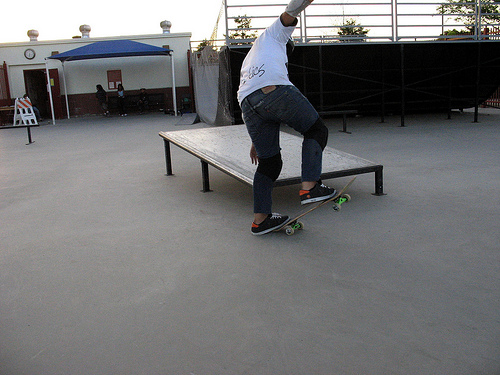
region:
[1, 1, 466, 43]
light in daytime sky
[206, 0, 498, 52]
railing on top of wall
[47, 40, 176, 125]
blue canvas on poles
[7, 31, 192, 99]
white wall of building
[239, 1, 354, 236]
person on tilted skateboard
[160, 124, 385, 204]
tilted surface on legs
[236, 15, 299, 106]
white short sleeved shirt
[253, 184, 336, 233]
two sneakers on feet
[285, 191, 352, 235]
wheels under tilted skateboard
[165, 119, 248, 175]
light reflection on ramp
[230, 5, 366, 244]
Man on a skateboard.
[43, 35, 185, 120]
Blue tent set up in front of a building.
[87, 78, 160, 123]
People under a blue tent.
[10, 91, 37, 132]
A safety sign in the background.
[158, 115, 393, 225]
A wooden skateboard ramp.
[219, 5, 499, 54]
Metal railing on bleachers.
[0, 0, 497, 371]
Man skating during the day.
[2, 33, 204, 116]
White building in a skate park.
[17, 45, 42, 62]
A clock on a wall.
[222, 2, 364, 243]
Man wearing blue jeans.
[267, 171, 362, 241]
black skateboard with black wheels and green metal accents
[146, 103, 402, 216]
short wooden surface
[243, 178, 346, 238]
pair of black and white skate sneakers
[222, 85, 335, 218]
pair of blue jeans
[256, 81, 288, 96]
brown leather patch on back of blue jeans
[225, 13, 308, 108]
white short sleeve t-shirt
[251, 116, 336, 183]
pair of black knee pads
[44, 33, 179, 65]
blue tent cover in front of building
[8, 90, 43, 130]
white traffic folding triangle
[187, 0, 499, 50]
metal elevated fence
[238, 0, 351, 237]
skateboarder performing trick in skate park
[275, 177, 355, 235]
skateboard with neon green wheel trucks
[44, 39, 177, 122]
small pavilion tent with blue top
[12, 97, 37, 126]
warning sign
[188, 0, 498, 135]
skateboard park half pipe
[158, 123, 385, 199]
feature in skateboard park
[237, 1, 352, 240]
skateboarder in white shirt and black pants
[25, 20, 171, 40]
silver aluminum exhaust vents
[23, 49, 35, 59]
outdoor round clock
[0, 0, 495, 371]
solitary skateboarder practicing in skate park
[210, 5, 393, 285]
Man skateboarding in park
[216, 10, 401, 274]
Man is off balance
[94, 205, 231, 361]
Cement is smooth with no cracks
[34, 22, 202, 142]
Tent on the concrete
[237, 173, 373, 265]
Skateboard lifted at an angle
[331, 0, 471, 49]
Fence around the park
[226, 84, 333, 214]
Man wearing skinny jeans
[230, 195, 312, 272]
Man wearing tennis shoes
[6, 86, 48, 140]
Caution sign by the tent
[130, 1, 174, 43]
The sky is cloudy